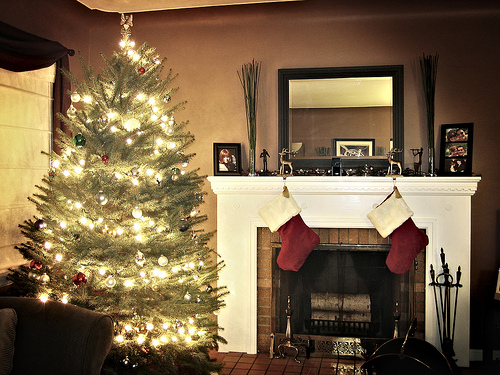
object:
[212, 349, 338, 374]
brick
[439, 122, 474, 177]
photos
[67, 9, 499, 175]
wall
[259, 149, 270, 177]
statue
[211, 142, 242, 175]
photo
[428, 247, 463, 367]
fireplace tools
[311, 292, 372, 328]
logs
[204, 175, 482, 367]
fireplace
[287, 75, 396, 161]
mirror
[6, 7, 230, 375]
christmas tree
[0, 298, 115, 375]
couch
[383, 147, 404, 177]
deer figurine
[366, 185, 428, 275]
stocking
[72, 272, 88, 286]
ornament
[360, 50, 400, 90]
ground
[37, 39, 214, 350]
lights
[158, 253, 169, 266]
ball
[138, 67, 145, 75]
ball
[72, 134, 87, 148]
ball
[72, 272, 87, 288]
ball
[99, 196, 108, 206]
ball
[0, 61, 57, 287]
brown drapes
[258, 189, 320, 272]
stocking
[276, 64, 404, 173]
framed mirror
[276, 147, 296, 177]
reindeer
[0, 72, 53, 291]
windws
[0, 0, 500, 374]
living room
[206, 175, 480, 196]
mantel